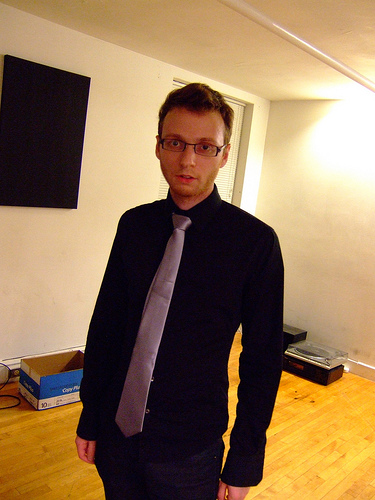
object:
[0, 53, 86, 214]
rectangle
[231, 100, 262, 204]
door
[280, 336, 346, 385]
record player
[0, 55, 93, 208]
board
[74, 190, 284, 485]
black shirt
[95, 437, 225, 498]
jeans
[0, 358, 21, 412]
black cord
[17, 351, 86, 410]
box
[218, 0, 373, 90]
tube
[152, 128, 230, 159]
glasses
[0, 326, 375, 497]
floors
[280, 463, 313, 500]
ground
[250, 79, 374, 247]
wall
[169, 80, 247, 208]
window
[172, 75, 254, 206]
blinds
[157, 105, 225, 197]
face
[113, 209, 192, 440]
tie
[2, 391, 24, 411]
cord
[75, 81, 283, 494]
man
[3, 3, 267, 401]
wall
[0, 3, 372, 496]
room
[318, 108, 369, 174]
light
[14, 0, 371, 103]
ceiling